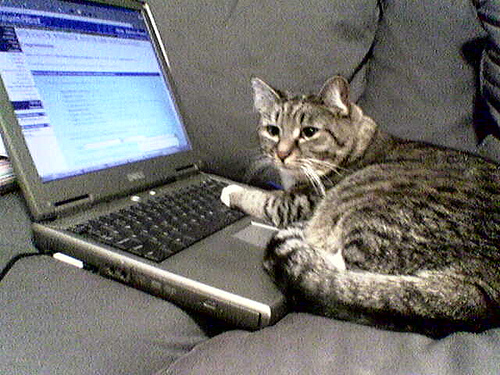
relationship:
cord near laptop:
[4, 247, 54, 282] [0, 0, 290, 330]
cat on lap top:
[241, 85, 486, 331] [3, 7, 318, 330]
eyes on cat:
[259, 124, 278, 137] [219, 76, 500, 330]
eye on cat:
[296, 125, 318, 141] [219, 76, 500, 330]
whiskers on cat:
[229, 146, 341, 191] [219, 76, 500, 330]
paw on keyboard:
[216, 154, 267, 236] [57, 174, 248, 271]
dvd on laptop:
[137, 264, 296, 351] [0, 1, 317, 332]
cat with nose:
[219, 76, 500, 330] [275, 140, 294, 160]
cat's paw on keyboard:
[219, 182, 253, 215] [61, 179, 254, 264]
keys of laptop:
[59, 177, 249, 265] [83, 180, 241, 258]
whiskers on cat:
[245, 155, 347, 199] [244, 79, 492, 373]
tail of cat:
[262, 220, 497, 326] [219, 76, 500, 330]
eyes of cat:
[259, 122, 324, 143] [231, 72, 480, 291]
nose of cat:
[275, 145, 290, 162] [219, 76, 500, 330]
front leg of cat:
[181, 165, 332, 228] [219, 76, 500, 330]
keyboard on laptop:
[34, 168, 259, 275] [0, 1, 317, 332]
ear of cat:
[316, 74, 351, 121] [319, 77, 361, 121]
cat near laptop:
[219, 76, 500, 330] [0, 1, 317, 332]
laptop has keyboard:
[7, 7, 256, 272] [118, 152, 268, 274]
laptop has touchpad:
[0, 0, 290, 330] [234, 221, 287, 249]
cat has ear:
[219, 76, 500, 330] [315, 72, 353, 115]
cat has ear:
[219, 76, 500, 330] [247, 70, 288, 113]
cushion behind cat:
[154, 2, 484, 169] [184, 80, 498, 309]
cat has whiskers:
[219, 76, 500, 330] [240, 157, 343, 206]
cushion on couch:
[136, 331, 495, 372] [9, 5, 491, 334]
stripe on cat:
[338, 222, 430, 254] [219, 76, 500, 330]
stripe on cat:
[339, 239, 388, 261] [219, 76, 500, 330]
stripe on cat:
[342, 257, 374, 271] [219, 76, 500, 330]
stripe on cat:
[358, 197, 472, 249] [219, 76, 500, 330]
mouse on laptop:
[224, 219, 287, 257] [0, 1, 317, 332]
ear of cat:
[316, 74, 363, 115] [219, 76, 500, 330]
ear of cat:
[244, 65, 279, 106] [219, 76, 500, 330]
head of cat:
[244, 74, 373, 181] [219, 76, 500, 330]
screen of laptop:
[3, 7, 173, 174] [0, 1, 317, 332]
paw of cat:
[216, 184, 249, 209] [219, 76, 500, 330]